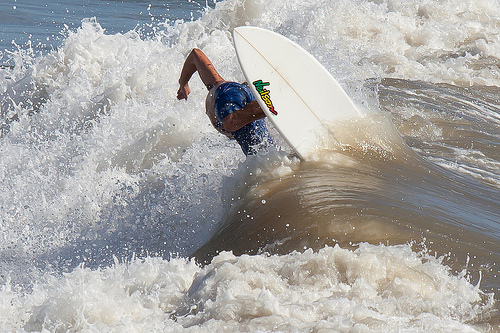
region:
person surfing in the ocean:
[126, 23, 356, 187]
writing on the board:
[249, 68, 284, 116]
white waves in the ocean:
[80, 108, 162, 175]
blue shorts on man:
[212, 73, 258, 128]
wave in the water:
[268, 188, 348, 243]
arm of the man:
[158, 46, 216, 86]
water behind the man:
[451, 98, 482, 148]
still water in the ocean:
[14, 3, 56, 43]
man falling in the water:
[188, 65, 252, 166]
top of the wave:
[263, 181, 358, 247]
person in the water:
[151, 27, 306, 207]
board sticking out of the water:
[227, 17, 397, 174]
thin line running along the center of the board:
[235, 27, 340, 132]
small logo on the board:
[247, 65, 284, 116]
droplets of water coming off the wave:
[137, 0, 157, 20]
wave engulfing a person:
[10, 11, 495, 326]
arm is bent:
[158, 37, 217, 110]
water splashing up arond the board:
[330, 107, 396, 149]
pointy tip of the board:
[222, 12, 257, 47]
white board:
[218, 21, 407, 205]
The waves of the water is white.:
[48, 63, 169, 225]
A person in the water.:
[161, 65, 268, 177]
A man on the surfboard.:
[153, 16, 290, 166]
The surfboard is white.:
[245, 28, 367, 157]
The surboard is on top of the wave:
[230, 21, 377, 195]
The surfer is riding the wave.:
[144, 11, 386, 180]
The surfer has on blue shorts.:
[208, 79, 256, 138]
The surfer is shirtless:
[169, 76, 214, 125]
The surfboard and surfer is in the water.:
[119, 19, 362, 176]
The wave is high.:
[132, 122, 432, 289]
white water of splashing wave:
[65, 21, 152, 78]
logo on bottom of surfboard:
[247, 73, 284, 123]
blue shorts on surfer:
[210, 80, 265, 155]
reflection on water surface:
[295, 164, 379, 221]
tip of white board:
[222, 24, 266, 51]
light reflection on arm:
[197, 48, 219, 79]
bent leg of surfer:
[213, 96, 267, 136]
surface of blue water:
[18, 1, 103, 27]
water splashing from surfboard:
[341, 99, 400, 155]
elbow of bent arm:
[177, 42, 209, 79]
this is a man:
[176, 47, 247, 162]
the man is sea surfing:
[175, 45, 278, 155]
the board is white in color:
[292, 74, 322, 114]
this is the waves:
[182, 149, 396, 312]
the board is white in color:
[280, 55, 310, 98]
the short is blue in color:
[216, 81, 248, 110]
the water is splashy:
[74, 80, 163, 164]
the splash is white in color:
[57, 37, 153, 133]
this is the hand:
[200, 53, 209, 73]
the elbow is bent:
[186, 42, 205, 69]